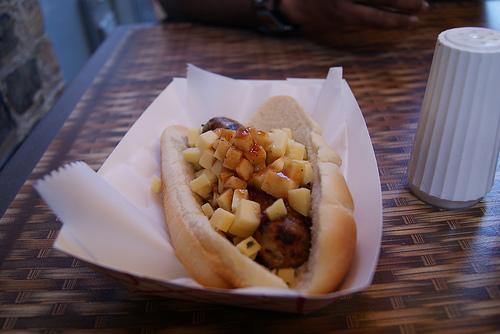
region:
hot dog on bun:
[147, 87, 362, 296]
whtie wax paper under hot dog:
[34, 55, 370, 292]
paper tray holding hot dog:
[48, 54, 399, 316]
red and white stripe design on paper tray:
[99, 267, 196, 309]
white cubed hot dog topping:
[196, 112, 321, 261]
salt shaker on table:
[403, 27, 497, 219]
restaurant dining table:
[3, 19, 498, 328]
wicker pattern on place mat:
[398, 231, 480, 333]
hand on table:
[281, 1, 439, 67]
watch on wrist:
[245, 2, 308, 42]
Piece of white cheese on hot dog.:
[263, 187, 291, 222]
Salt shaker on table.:
[398, 112, 463, 216]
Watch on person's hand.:
[253, 8, 283, 25]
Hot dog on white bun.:
[243, 206, 353, 290]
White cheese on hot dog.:
[202, 208, 237, 230]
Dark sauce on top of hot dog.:
[223, 114, 268, 188]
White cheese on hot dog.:
[191, 128, 224, 163]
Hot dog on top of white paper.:
[117, 173, 218, 290]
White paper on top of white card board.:
[66, 148, 151, 235]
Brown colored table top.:
[29, 267, 76, 326]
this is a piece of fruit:
[281, 180, 313, 225]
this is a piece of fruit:
[226, 210, 261, 250]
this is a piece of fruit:
[190, 163, 224, 223]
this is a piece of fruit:
[271, 124, 295, 162]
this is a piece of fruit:
[186, 125, 223, 165]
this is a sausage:
[209, 105, 311, 265]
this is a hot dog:
[155, 85, 348, 302]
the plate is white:
[74, 49, 405, 309]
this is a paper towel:
[54, 45, 394, 304]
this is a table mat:
[314, 49, 443, 259]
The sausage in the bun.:
[182, 113, 308, 269]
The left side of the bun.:
[167, 127, 253, 282]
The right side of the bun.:
[265, 95, 362, 290]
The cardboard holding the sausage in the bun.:
[51, 60, 376, 300]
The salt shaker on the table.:
[415, 20, 497, 207]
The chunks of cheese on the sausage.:
[188, 120, 310, 261]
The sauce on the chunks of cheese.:
[207, 121, 284, 200]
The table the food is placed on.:
[4, 18, 464, 328]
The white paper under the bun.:
[35, 53, 357, 292]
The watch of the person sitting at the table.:
[256, 3, 286, 38]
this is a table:
[90, 57, 117, 76]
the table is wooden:
[36, 124, 53, 130]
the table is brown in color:
[10, 147, 31, 159]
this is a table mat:
[400, 254, 443, 284]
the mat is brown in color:
[408, 224, 448, 285]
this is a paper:
[71, 191, 128, 233]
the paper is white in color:
[92, 203, 109, 224]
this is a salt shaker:
[454, 37, 481, 192]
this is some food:
[153, 98, 320, 282]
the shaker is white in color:
[447, 78, 467, 123]